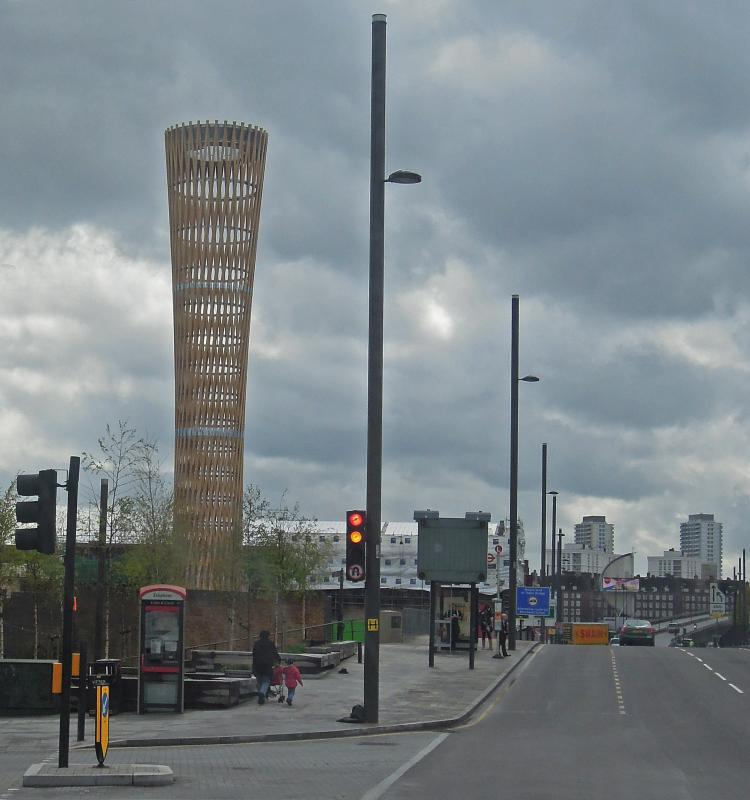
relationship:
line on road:
[607, 642, 632, 719] [453, 642, 725, 797]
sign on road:
[514, 583, 560, 622] [453, 642, 725, 797]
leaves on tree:
[267, 531, 316, 585] [247, 501, 323, 651]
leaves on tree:
[121, 553, 153, 581] [112, 511, 204, 592]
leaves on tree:
[117, 496, 156, 550] [98, 432, 182, 594]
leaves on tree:
[269, 531, 316, 563] [237, 488, 318, 643]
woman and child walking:
[241, 623, 286, 708] [258, 679, 287, 755]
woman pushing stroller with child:
[241, 623, 272, 708] [281, 662, 305, 721]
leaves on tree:
[52, 560, 155, 662] [42, 475, 366, 678]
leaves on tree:
[217, 505, 300, 605] [115, 469, 483, 700]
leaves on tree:
[229, 516, 339, 691] [280, 484, 342, 579]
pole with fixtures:
[324, 0, 422, 731] [356, 163, 466, 225]